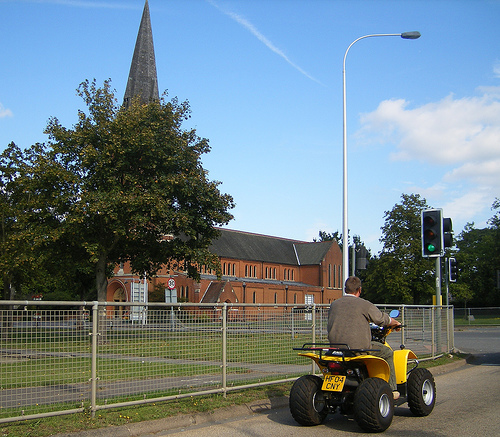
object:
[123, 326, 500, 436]
road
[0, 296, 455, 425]
fence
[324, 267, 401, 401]
man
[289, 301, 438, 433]
atv